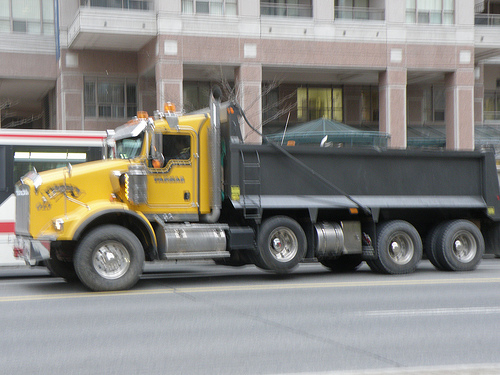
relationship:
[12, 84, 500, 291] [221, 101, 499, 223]
truck has dump bed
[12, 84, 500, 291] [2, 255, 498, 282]
truck next curb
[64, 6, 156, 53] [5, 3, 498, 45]
balcony on second floor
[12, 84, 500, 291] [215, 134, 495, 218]
truck has dump bed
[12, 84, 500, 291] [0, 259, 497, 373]
truck on road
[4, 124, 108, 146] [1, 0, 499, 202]
stripe painted on building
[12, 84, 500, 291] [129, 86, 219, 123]
truck has lights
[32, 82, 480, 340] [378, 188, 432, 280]
truck has a tire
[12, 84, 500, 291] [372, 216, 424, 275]
truck has a tire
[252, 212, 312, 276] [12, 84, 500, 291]
tire on truck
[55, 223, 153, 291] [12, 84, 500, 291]
tire on truck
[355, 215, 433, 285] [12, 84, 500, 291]
tire on truck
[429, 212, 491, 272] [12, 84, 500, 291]
tire on truck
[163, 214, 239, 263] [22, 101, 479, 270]
fuel tank on dump truck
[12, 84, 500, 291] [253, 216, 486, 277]
truck has tires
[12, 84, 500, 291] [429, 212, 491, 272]
truck has a tire